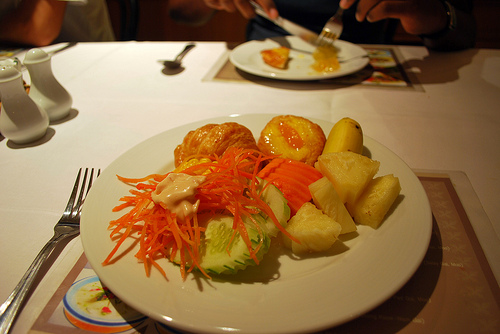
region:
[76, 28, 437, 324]
food on white plates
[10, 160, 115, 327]
fork next to plate and placemat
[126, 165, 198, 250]
creamy dressing on shredded carrots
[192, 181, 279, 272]
cucumber slices with green edging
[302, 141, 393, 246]
triangular pieces of pineapple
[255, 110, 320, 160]
glistening scallop with orange flavoring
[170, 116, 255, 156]
small flaky croissant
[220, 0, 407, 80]
diner using knife and fork to finish meal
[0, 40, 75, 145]
salt and pepper in curved ceramic containers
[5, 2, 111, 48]
person resting elbow on table edge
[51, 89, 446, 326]
a plate on the table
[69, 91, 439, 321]
the plate is round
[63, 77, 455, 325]
a plate of food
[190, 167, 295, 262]
2 cut cucumbers on the plate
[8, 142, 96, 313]
the fork on the left side of the plate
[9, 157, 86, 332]
the fork is silver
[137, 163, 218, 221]
a dollop of salad dressing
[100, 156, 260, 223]
shredded carrots on top of cucumbers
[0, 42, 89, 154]
a salt and pepper shaker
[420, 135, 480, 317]
a paper placemat under the plate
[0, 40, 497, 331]
a white cloth covering a table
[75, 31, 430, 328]
two plates with food on them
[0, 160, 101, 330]
fork partially hidden by plate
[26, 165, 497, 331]
place mat beneath plate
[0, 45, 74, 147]
white spice shakers on table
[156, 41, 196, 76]
spoon laying on table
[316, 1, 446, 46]
a hand holding a fork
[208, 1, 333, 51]
a hand holding a knife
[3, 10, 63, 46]
an elbow on the table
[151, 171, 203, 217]
sauce on shredded carrots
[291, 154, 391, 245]
triangular - shaped pineapple chunks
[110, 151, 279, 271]
sliced cucumbers with shredded carrots and sauce on top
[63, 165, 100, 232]
fork tines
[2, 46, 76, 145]
white salt and pepper shakers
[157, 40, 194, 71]
spoon sitting across the table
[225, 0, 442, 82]
person sitting across the table cutting their food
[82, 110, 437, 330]
food sitting on a white plate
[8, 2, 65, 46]
a person's left elbow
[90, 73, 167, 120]
section of white table cloth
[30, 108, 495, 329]
plate sitting on a placemat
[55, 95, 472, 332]
a meal on a plate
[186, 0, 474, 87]
a man cutting food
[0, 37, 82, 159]
salt and pepper shakers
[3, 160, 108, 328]
a silver colored metal fork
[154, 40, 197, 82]
a silver colored spood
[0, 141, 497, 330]
a plate sitting on a place mat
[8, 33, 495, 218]
a white table cloth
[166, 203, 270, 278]
slices of cucumber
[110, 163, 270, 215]
shredded carrots with a creamy topping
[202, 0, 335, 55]
a knife being held by a man